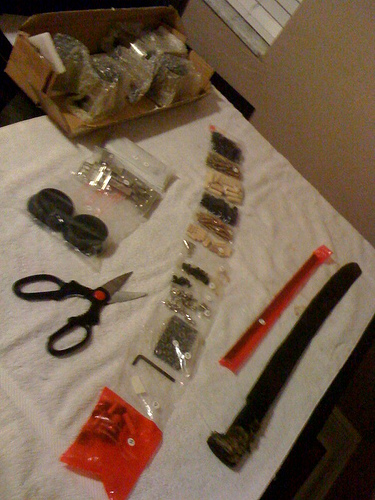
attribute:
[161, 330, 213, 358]
beads — small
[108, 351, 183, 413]
plastic bags — clear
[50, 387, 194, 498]
packet — red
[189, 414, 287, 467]
handle — messed up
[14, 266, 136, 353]
kitchen scissors — black, silver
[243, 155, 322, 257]
cloth — white 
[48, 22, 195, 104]
items —  small, groups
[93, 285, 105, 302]
dot — red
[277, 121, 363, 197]
floor —  multi-colored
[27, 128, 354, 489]
tools — some,  laid, out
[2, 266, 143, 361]
scissors —  red, black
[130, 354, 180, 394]
wrench — L 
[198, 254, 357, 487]
knife — long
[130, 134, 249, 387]
packets — little 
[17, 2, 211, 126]
box — cardboard, filled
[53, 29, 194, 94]
items — wrapped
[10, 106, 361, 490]
towel — white, under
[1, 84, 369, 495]
towel — white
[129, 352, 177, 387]
tool — small, brown, furniture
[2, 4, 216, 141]
box — open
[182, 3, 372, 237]
wall — beige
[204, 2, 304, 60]
blinds — closed